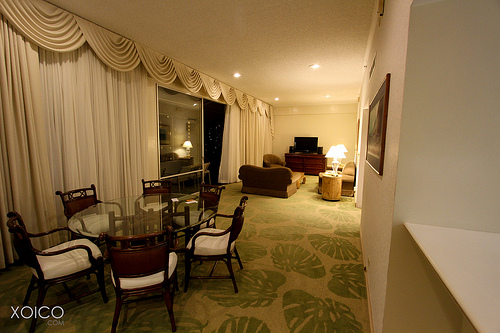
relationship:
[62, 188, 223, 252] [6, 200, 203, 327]
table near chairs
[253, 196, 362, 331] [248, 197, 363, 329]
carpet on floor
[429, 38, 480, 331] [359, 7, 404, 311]
inset in wall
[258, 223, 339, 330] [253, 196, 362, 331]
pattern on carpet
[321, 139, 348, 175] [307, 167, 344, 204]
lamps on side table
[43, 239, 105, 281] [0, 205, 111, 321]
cushion in chair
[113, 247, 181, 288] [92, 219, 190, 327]
seat in chair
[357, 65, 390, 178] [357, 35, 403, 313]
painting hanging on wall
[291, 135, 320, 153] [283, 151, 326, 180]
tv on chest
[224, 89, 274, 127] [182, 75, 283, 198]
draping over curtains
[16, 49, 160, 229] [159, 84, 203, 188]
curtains on windows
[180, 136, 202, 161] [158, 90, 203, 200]
lamp reflection in window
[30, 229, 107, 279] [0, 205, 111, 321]
cushion in chair